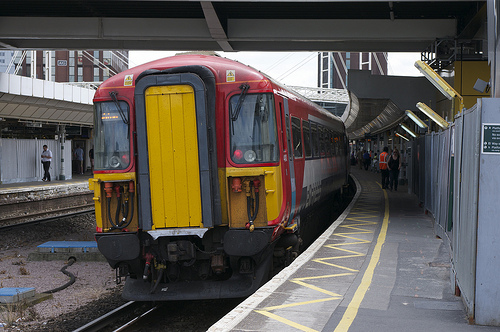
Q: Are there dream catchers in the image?
A: No, there are no dream catchers.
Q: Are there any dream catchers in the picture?
A: No, there are no dream catchers.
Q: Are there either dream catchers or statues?
A: No, there are no dream catchers or statues.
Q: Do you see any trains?
A: Yes, there is a train.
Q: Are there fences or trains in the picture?
A: Yes, there is a train.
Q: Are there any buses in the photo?
A: No, there are no buses.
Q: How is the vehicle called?
A: The vehicle is a train.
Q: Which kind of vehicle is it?
A: The vehicle is a train.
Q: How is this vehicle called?
A: This is a train.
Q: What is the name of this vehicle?
A: This is a train.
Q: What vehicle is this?
A: This is a train.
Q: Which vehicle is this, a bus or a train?
A: This is a train.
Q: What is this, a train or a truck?
A: This is a train.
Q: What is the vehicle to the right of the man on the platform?
A: The vehicle is a train.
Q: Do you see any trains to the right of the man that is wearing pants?
A: Yes, there is a train to the right of the man.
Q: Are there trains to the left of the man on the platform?
A: No, the train is to the right of the man.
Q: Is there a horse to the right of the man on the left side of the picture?
A: No, there is a train to the right of the man.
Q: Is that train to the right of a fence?
A: No, the train is to the right of the man.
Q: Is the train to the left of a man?
A: No, the train is to the right of a man.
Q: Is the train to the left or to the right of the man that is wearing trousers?
A: The train is to the right of the man.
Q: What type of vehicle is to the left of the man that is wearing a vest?
A: The vehicle is a train.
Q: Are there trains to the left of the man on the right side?
A: Yes, there is a train to the left of the man.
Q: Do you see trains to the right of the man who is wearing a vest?
A: No, the train is to the left of the man.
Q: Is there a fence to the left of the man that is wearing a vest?
A: No, there is a train to the left of the man.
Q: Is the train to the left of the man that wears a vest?
A: Yes, the train is to the left of the man.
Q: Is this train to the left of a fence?
A: No, the train is to the left of the man.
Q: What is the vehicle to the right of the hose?
A: The vehicle is a train.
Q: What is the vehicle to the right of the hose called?
A: The vehicle is a train.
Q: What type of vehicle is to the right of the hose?
A: The vehicle is a train.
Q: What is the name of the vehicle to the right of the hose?
A: The vehicle is a train.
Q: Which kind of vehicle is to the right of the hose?
A: The vehicle is a train.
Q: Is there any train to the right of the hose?
A: Yes, there is a train to the right of the hose.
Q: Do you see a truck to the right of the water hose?
A: No, there is a train to the right of the water hose.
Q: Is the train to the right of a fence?
A: No, the train is to the right of a hose.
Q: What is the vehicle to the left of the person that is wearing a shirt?
A: The vehicle is a train.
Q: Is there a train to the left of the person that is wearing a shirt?
A: Yes, there is a train to the left of the person.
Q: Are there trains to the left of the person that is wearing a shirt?
A: Yes, there is a train to the left of the person.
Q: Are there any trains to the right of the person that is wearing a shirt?
A: No, the train is to the left of the person.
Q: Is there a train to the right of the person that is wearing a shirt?
A: No, the train is to the left of the person.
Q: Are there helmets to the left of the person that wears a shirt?
A: No, there is a train to the left of the person.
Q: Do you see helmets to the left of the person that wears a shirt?
A: No, there is a train to the left of the person.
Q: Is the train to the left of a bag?
A: No, the train is to the left of the person.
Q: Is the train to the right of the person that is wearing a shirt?
A: No, the train is to the left of the person.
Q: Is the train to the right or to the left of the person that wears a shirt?
A: The train is to the left of the person.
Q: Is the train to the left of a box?
A: No, the train is to the right of a box.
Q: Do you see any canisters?
A: No, there are no canisters.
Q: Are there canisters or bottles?
A: No, there are no canisters or bottles.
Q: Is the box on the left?
A: Yes, the box is on the left of the image.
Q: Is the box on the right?
A: No, the box is on the left of the image.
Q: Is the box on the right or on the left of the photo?
A: The box is on the left of the image.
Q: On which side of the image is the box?
A: The box is on the left of the image.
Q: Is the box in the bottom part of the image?
A: Yes, the box is in the bottom of the image.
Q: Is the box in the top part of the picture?
A: No, the box is in the bottom of the image.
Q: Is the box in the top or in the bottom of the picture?
A: The box is in the bottom of the image.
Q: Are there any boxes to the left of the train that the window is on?
A: Yes, there is a box to the left of the train.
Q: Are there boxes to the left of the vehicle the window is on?
A: Yes, there is a box to the left of the train.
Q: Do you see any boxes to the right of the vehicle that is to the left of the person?
A: No, the box is to the left of the train.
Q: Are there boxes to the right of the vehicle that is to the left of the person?
A: No, the box is to the left of the train.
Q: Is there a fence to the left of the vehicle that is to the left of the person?
A: No, there is a box to the left of the train.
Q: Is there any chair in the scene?
A: No, there are no chairs.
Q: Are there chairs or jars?
A: No, there are no chairs or jars.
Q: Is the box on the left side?
A: Yes, the box is on the left of the image.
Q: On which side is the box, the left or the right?
A: The box is on the left of the image.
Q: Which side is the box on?
A: The box is on the left of the image.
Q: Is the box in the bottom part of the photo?
A: Yes, the box is in the bottom of the image.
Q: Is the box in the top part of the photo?
A: No, the box is in the bottom of the image.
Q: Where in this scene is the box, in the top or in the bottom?
A: The box is in the bottom of the image.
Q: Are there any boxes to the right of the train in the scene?
A: No, the box is to the left of the train.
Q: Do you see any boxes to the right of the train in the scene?
A: No, the box is to the left of the train.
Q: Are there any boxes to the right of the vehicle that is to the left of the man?
A: No, the box is to the left of the train.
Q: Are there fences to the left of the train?
A: No, there is a box to the left of the train.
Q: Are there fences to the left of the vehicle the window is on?
A: No, there is a box to the left of the train.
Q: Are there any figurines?
A: No, there are no figurines.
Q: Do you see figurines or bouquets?
A: No, there are no figurines or bouquets.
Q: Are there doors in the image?
A: Yes, there are doors.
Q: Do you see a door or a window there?
A: Yes, there are doors.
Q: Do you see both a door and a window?
A: Yes, there are both a door and a window.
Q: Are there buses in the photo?
A: No, there are no buses.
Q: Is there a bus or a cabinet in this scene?
A: No, there are no buses or cabinets.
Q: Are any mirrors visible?
A: No, there are no mirrors.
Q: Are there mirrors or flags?
A: No, there are no mirrors or flags.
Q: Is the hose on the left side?
A: Yes, the hose is on the left of the image.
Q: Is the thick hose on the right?
A: No, the hose is on the left of the image.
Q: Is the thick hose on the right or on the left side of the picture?
A: The water hose is on the left of the image.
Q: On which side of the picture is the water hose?
A: The water hose is on the left of the image.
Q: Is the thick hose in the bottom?
A: Yes, the water hose is in the bottom of the image.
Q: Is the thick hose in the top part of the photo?
A: No, the hose is in the bottom of the image.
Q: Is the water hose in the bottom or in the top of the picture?
A: The water hose is in the bottom of the image.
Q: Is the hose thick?
A: Yes, the hose is thick.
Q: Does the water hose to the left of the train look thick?
A: Yes, the water hose is thick.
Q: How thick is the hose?
A: The hose is thick.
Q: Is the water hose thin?
A: No, the water hose is thick.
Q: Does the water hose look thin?
A: No, the water hose is thick.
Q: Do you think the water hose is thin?
A: No, the water hose is thick.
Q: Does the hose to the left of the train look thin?
A: No, the water hose is thick.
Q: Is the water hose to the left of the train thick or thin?
A: The water hose is thick.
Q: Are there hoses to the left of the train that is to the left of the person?
A: Yes, there is a hose to the left of the train.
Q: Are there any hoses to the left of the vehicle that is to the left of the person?
A: Yes, there is a hose to the left of the train.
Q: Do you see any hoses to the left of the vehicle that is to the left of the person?
A: Yes, there is a hose to the left of the train.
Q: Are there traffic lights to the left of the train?
A: No, there is a hose to the left of the train.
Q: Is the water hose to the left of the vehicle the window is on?
A: Yes, the water hose is to the left of the train.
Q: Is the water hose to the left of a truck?
A: No, the water hose is to the left of the train.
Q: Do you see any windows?
A: Yes, there is a window.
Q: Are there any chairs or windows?
A: Yes, there is a window.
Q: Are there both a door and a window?
A: Yes, there are both a window and a door.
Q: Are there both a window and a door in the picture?
A: Yes, there are both a window and a door.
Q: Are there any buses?
A: No, there are no buses.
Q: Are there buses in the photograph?
A: No, there are no buses.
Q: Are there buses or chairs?
A: No, there are no buses or chairs.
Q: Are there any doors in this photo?
A: Yes, there is a door.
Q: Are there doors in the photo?
A: Yes, there is a door.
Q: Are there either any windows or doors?
A: Yes, there is a door.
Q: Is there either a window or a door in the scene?
A: Yes, there is a door.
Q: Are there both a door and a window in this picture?
A: Yes, there are both a door and a window.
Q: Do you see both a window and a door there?
A: Yes, there are both a door and a window.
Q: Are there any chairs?
A: No, there are no chairs.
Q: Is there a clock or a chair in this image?
A: No, there are no chairs or clocks.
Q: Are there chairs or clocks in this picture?
A: No, there are no chairs or clocks.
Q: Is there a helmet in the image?
A: No, there are no helmets.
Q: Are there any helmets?
A: No, there are no helmets.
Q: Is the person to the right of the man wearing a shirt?
A: Yes, the person is wearing a shirt.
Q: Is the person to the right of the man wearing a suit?
A: No, the person is wearing a shirt.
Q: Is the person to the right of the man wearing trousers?
A: Yes, the person is wearing trousers.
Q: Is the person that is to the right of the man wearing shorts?
A: No, the person is wearing trousers.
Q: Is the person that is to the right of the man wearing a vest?
A: Yes, the person is wearing a vest.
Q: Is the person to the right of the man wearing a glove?
A: No, the person is wearing a vest.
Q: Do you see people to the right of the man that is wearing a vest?
A: Yes, there is a person to the right of the man.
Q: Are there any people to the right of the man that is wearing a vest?
A: Yes, there is a person to the right of the man.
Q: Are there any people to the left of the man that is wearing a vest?
A: No, the person is to the right of the man.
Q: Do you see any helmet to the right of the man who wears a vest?
A: No, there is a person to the right of the man.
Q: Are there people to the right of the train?
A: Yes, there is a person to the right of the train.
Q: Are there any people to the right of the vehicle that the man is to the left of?
A: Yes, there is a person to the right of the train.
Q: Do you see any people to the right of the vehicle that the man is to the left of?
A: Yes, there is a person to the right of the train.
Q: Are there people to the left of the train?
A: No, the person is to the right of the train.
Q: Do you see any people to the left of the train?
A: No, the person is to the right of the train.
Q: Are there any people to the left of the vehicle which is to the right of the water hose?
A: No, the person is to the right of the train.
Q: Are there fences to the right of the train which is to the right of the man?
A: No, there is a person to the right of the train.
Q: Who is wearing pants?
A: The man is wearing pants.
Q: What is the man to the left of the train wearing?
A: The man is wearing trousers.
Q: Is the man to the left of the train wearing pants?
A: Yes, the man is wearing pants.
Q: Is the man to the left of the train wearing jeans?
A: No, the man is wearing pants.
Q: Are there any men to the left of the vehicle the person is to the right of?
A: Yes, there is a man to the left of the train.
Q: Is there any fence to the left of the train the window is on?
A: No, there is a man to the left of the train.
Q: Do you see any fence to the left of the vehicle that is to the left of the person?
A: No, there is a man to the left of the train.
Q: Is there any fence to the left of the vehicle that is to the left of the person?
A: No, there is a man to the left of the train.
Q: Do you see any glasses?
A: No, there are no glasses.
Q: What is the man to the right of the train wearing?
A: The man is wearing a vest.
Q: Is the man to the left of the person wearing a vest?
A: Yes, the man is wearing a vest.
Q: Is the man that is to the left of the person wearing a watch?
A: No, the man is wearing a vest.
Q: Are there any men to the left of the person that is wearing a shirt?
A: Yes, there is a man to the left of the person.